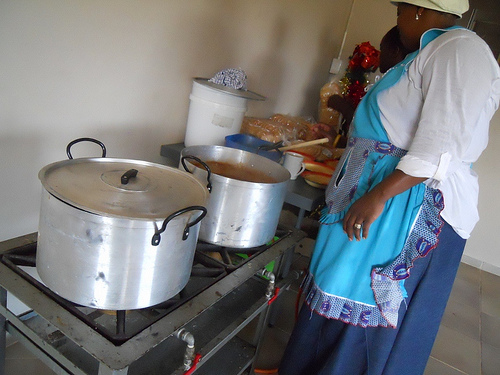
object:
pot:
[36, 155, 212, 311]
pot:
[176, 147, 290, 250]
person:
[282, 2, 499, 374]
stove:
[0, 213, 305, 373]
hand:
[339, 193, 381, 241]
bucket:
[183, 78, 247, 152]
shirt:
[379, 28, 499, 242]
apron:
[301, 25, 477, 326]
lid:
[41, 157, 207, 218]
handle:
[149, 207, 209, 246]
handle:
[66, 136, 107, 161]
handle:
[180, 153, 213, 191]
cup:
[281, 152, 306, 181]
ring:
[354, 221, 362, 228]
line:
[176, 330, 196, 374]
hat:
[388, 0, 468, 20]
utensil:
[264, 136, 328, 153]